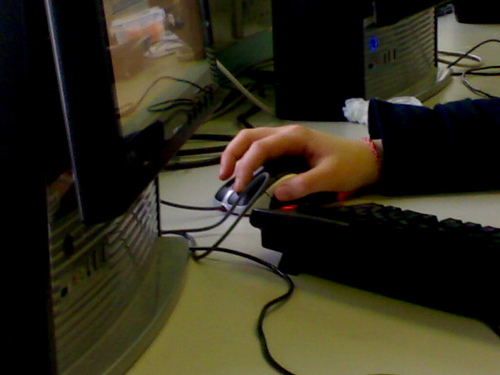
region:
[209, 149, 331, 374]
a mouse with a wire.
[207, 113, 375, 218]
a hand on top of a mouse.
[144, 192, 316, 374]
a wire on a mouse.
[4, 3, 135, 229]
a small desk top computer.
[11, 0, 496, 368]
a desk with clutter on it.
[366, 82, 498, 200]
a dark shirt sleeve.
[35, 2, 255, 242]
a computer monitor on a desk.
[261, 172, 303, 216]
a human thumb.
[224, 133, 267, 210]
a human finger.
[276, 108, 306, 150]
a human knuckle.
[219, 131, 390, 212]
A hand on a computer mouse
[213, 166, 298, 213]
A wired computer mouse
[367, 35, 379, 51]
A blue LED light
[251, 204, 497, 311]
A keyboard to a computer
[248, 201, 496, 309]
A keyboard connected to a computer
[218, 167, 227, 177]
A short cut fingernail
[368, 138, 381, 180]
A pink bracelet on a wrist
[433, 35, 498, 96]
Wires connected to a computer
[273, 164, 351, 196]
A person's thumb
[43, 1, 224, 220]
A computer monitor with a display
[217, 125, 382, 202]
right hand of a person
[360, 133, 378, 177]
small pink bracelet on wrist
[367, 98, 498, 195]
dark long sleeve on the arm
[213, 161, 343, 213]
computer mouse under person's hand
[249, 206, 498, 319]
computer keyboard on the desk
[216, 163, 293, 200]
no nail polish on fingernails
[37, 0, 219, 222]
computer screen is on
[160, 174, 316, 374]
black cord for mouse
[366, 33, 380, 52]
blue light on computer modem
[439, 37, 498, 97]
power cords on the desk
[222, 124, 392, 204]
hand on the PC mouse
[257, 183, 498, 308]
pc keyboard under hand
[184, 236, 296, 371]
cable leading from the mouse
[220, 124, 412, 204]
a persons right hand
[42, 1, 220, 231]
a Pc monitor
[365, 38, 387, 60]
a blue light on the PC CPU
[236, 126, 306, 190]
the index finger pressing a mouse button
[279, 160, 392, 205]
right thumb on the side of the PC mouse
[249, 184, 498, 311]
a black PC keyboard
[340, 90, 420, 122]
wrapper to the right of the arm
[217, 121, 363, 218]
a hand holding a mouse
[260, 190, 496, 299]
a black key board on a desk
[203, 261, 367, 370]
a white desk top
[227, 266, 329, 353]
a wire on the desk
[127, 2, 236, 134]
a reflection on the screen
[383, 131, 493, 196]
a black shirt sleeve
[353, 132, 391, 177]
a pink bracelet on a wrist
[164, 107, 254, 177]
a black cable on the desk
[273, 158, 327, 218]
a thumb on a right hand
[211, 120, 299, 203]
a couple of fingers on a hand